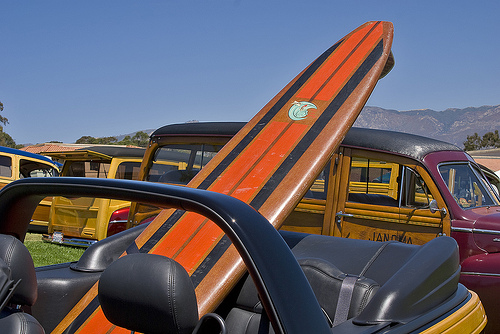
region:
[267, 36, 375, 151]
orange and black surfboard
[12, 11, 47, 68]
white clouds in blue sky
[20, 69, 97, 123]
white clouds in blue sky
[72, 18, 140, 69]
white clouds in blue sky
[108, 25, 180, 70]
white clouds in blue sky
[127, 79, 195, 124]
white clouds in blue sky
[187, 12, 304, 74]
white clouds in blue sky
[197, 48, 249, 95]
white clouds in blue sky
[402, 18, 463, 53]
white clouds in blue sky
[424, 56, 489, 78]
white clouds in blue sky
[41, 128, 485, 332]
The car has the top down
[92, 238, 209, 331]
The head rest on the seat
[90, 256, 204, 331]
The head rest is the color gray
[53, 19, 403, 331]
The surfboard is the color orange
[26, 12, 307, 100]
The sky is clear and blue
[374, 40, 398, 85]
The fin on the surfboard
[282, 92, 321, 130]
The logo on the surfboard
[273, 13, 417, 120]
The top of the surfboard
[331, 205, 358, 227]
The door handle is silver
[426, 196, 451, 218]
The rear view mirror is silver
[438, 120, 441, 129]
part of a hill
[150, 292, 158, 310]
part of a seat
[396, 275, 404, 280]
edge of a seat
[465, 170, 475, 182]
part of a window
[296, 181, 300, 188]
part of a board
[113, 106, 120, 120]
part of the sky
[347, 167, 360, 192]
part of a door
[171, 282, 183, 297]
part of a seat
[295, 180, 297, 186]
edge of a board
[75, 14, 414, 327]
orange and black surf board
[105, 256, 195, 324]
a black head rest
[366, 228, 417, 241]
black writing on a door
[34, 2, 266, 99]
a clear blue sky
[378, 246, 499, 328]
black and yellow on a car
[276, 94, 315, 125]
a symbol on the board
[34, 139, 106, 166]
a back glass open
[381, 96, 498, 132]
a gray mountain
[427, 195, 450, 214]
a silver mirror on a car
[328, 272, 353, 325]
a seat belt in a car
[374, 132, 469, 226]
red and brown truck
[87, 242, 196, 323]
black car head rest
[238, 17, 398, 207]
orange and black surf board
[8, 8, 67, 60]
white clouds against blue sky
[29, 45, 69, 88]
white clouds against blue sky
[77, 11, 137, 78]
white clouds against blue sky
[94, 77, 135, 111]
white clouds against blue sky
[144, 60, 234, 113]
white clouds against blue sky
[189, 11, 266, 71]
white clouds against blue sky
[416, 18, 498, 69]
white clouds against blue sky